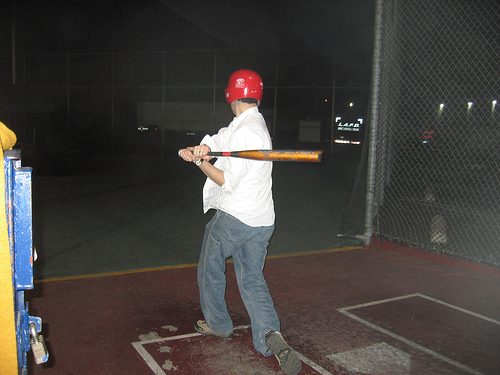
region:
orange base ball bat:
[238, 143, 327, 168]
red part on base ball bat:
[220, 150, 237, 160]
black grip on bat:
[186, 150, 222, 164]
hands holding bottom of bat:
[179, 141, 214, 162]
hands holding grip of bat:
[179, 143, 217, 167]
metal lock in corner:
[34, 323, 55, 355]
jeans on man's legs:
[195, 208, 284, 357]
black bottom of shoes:
[263, 330, 301, 374]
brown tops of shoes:
[203, 316, 218, 342]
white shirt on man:
[220, 108, 282, 205]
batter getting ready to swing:
[198, 149, 333, 161]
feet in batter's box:
[144, 328, 301, 374]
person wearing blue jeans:
[216, 208, 313, 338]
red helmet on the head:
[205, 64, 278, 109]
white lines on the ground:
[336, 260, 472, 374]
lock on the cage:
[20, 315, 54, 363]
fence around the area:
[392, 0, 499, 266]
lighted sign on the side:
[334, 104, 362, 166]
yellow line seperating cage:
[36, 257, 201, 282]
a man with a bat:
[126, 46, 351, 373]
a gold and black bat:
[169, 131, 383, 204]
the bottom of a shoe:
[259, 327, 306, 372]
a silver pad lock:
[21, 320, 59, 370]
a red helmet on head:
[198, 64, 280, 114]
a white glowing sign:
[332, 114, 372, 142]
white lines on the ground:
[122, 299, 495, 373]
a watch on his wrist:
[191, 153, 214, 172]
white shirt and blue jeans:
[167, 84, 317, 351]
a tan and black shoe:
[183, 313, 253, 353]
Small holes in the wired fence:
[368, 204, 403, 241]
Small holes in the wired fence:
[396, 205, 424, 244]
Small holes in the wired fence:
[440, 216, 479, 261]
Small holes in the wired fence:
[460, 143, 498, 183]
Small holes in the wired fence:
[411, 100, 441, 134]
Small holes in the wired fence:
[375, 36, 410, 71]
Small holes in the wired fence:
[422, 21, 451, 78]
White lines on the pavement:
[328, 279, 455, 374]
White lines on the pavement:
[96, 309, 289, 372]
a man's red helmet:
[221, 67, 264, 104]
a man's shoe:
[262, 330, 302, 371]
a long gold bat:
[200, 146, 325, 166]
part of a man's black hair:
[236, 95, 254, 102]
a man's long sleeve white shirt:
[194, 105, 284, 227]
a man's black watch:
[192, 155, 206, 167]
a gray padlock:
[26, 325, 51, 367]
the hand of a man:
[190, 145, 214, 155]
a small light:
[436, 100, 448, 110]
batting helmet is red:
[224, 64, 263, 108]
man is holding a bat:
[187, 139, 327, 168]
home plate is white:
[325, 335, 418, 372]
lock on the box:
[24, 320, 50, 365]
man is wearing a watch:
[192, 154, 211, 170]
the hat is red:
[224, 78, 252, 101]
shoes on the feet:
[191, 305, 286, 358]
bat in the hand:
[199, 148, 319, 160]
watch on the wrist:
[192, 156, 209, 168]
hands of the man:
[165, 140, 209, 161]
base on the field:
[330, 337, 407, 367]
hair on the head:
[245, 98, 260, 105]